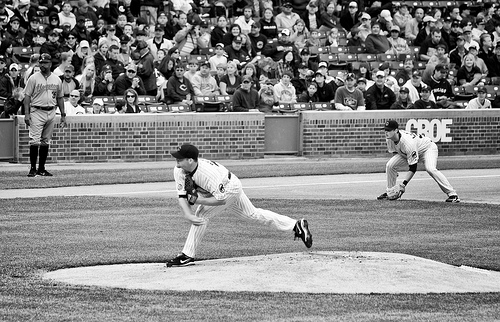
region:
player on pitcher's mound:
[143, 123, 332, 271]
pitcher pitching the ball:
[151, 134, 321, 276]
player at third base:
[363, 109, 463, 219]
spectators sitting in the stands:
[42, 9, 491, 96]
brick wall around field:
[61, 108, 492, 156]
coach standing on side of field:
[19, 46, 76, 183]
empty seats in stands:
[307, 28, 397, 76]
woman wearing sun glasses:
[117, 86, 143, 111]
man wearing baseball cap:
[165, 130, 205, 172]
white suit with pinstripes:
[185, 162, 308, 275]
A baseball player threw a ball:
[167, 141, 314, 269]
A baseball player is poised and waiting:
[376, 117, 461, 203]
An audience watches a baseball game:
[74, 0, 494, 112]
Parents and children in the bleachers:
[167, 53, 304, 101]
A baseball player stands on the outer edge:
[20, 52, 66, 179]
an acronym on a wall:
[405, 116, 452, 142]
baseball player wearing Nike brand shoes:
[165, 250, 196, 267]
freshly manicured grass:
[0, 195, 149, 320]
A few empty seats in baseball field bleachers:
[305, 42, 427, 74]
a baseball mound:
[232, 245, 487, 299]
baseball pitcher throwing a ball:
[156, 137, 326, 274]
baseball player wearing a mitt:
[378, 115, 467, 211]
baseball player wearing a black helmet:
[14, 50, 73, 188]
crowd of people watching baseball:
[83, 14, 498, 93]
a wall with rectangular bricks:
[78, 113, 166, 164]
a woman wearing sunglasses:
[121, 90, 146, 115]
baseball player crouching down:
[376, 115, 469, 206]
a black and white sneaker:
[293, 213, 319, 252]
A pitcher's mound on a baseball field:
[55, 248, 491, 313]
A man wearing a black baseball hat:
[171, 141, 202, 174]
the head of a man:
[172, 140, 203, 172]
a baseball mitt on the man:
[181, 171, 200, 207]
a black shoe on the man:
[291, 213, 317, 250]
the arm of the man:
[198, 173, 225, 210]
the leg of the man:
[224, 191, 295, 243]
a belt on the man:
[223, 167, 236, 180]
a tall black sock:
[36, 142, 53, 168]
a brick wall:
[0, 107, 499, 170]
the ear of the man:
[186, 155, 193, 164]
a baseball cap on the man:
[168, 140, 199, 160]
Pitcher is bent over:
[167, 144, 310, 277]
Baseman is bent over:
[370, 115, 458, 204]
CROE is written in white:
[406, 117, 454, 138]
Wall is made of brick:
[88, 123, 264, 158]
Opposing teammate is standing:
[18, 55, 68, 172]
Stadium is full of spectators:
[46, 1, 486, 104]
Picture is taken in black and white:
[1, 1, 498, 318]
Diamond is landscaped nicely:
[53, 247, 499, 301]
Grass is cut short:
[11, 202, 151, 255]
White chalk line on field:
[249, 171, 373, 188]